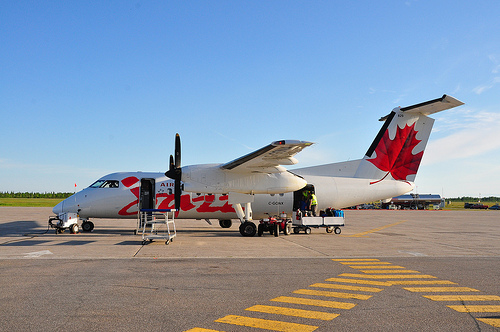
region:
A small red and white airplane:
[37, 75, 477, 240]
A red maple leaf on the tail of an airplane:
[361, 115, 436, 205]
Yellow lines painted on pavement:
[205, 246, 495, 326]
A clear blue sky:
[50, 15, 295, 85]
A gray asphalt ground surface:
[40, 260, 195, 300]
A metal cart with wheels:
[125, 200, 185, 255]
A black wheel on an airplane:
[235, 205, 260, 235]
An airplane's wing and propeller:
[150, 125, 315, 220]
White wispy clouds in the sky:
[450, 113, 497, 175]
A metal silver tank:
[387, 183, 442, 214]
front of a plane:
[50, 151, 151, 233]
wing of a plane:
[239, 122, 317, 170]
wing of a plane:
[422, 69, 480, 141]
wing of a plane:
[369, 99, 443, 171]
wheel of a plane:
[232, 219, 269, 243]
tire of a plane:
[70, 225, 105, 243]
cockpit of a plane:
[59, 161, 143, 229]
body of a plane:
[163, 132, 345, 223]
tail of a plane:
[342, 143, 443, 213]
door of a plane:
[287, 176, 319, 207]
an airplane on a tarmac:
[24, 81, 469, 244]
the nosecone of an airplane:
[43, 195, 63, 216]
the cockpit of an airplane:
[86, 173, 125, 192]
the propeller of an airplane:
[163, 129, 185, 214]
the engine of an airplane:
[166, 161, 332, 197]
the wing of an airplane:
[223, 129, 317, 176]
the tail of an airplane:
[353, 78, 469, 219]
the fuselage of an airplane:
[120, 151, 347, 250]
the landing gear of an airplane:
[218, 216, 260, 238]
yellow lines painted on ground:
[192, 254, 499, 330]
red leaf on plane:
[355, 124, 418, 186]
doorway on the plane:
[142, 175, 156, 206]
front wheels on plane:
[81, 218, 95, 234]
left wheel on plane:
[240, 218, 259, 239]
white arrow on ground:
[0, 245, 82, 259]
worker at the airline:
[311, 192, 322, 211]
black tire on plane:
[216, 215, 233, 230]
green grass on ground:
[18, 198, 50, 207]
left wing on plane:
[225, 135, 315, 163]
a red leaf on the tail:
[366, 121, 424, 186]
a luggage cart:
[141, 205, 177, 241]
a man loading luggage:
[304, 189, 322, 217]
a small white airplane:
[52, 93, 465, 230]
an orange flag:
[72, 180, 79, 188]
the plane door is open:
[136, 176, 155, 216]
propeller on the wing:
[167, 133, 184, 211]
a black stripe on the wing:
[225, 144, 274, 167]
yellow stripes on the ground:
[193, 258, 498, 330]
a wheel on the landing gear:
[240, 220, 255, 238]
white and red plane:
[57, 87, 461, 231]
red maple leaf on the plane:
[357, 120, 421, 182]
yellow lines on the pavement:
[194, 223, 498, 330]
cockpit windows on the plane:
[90, 177, 115, 189]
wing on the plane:
[223, 133, 302, 183]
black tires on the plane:
[56, 215, 256, 242]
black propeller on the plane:
[162, 121, 191, 217]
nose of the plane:
[48, 184, 76, 221]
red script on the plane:
[117, 189, 237, 220]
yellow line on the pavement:
[220, 298, 257, 328]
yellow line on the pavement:
[252, 289, 304, 330]